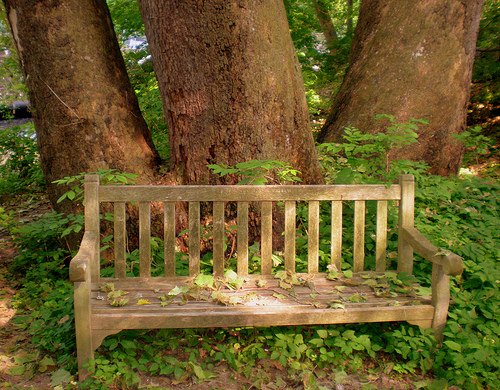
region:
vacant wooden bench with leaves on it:
[66, 171, 458, 378]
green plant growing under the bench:
[86, 328, 433, 376]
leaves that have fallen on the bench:
[91, 264, 423, 311]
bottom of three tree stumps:
[10, 38, 469, 260]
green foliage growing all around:
[0, 113, 499, 388]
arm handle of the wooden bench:
[400, 227, 460, 352]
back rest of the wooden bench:
[82, 171, 416, 281]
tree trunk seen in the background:
[313, 1, 343, 86]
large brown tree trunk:
[139, 1, 330, 257]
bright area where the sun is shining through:
[235, 292, 300, 314]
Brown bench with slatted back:
[66, 164, 457, 355]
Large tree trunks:
[5, 1, 466, 165]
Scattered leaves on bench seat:
[130, 265, 429, 314]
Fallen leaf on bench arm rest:
[436, 245, 452, 270]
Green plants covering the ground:
[442, 182, 496, 245]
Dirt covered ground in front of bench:
[162, 379, 399, 387]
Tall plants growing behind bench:
[321, 107, 431, 196]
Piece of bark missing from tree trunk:
[3, 6, 41, 68]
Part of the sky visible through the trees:
[120, 27, 151, 76]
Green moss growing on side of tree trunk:
[254, 17, 298, 127]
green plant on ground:
[443, 191, 473, 221]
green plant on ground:
[459, 351, 489, 374]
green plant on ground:
[317, 351, 344, 367]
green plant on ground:
[214, 348, 257, 372]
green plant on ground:
[165, 360, 202, 380]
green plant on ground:
[116, 348, 153, 373]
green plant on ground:
[29, 330, 59, 366]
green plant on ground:
[44, 300, 74, 331]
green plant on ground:
[16, 231, 52, 275]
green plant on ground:
[367, 128, 409, 173]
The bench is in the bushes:
[70, 172, 451, 364]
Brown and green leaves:
[100, 262, 420, 309]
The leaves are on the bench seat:
[96, 260, 411, 312]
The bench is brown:
[60, 172, 450, 378]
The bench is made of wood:
[60, 165, 460, 371]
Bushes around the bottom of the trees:
[27, 120, 483, 355]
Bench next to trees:
[15, 35, 480, 385]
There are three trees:
[12, 29, 471, 224]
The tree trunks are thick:
[16, 28, 476, 225]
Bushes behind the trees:
[121, 34, 354, 156]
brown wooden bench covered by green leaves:
[74, 178, 149, 368]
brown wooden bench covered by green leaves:
[149, 177, 247, 319]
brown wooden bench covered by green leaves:
[230, 187, 314, 317]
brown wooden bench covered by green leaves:
[318, 177, 431, 330]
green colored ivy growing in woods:
[459, 323, 485, 373]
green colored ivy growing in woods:
[470, 234, 490, 283]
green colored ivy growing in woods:
[442, 192, 475, 225]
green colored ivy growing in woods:
[469, 182, 495, 222]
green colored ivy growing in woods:
[309, 335, 363, 362]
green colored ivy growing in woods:
[418, 174, 451, 208]